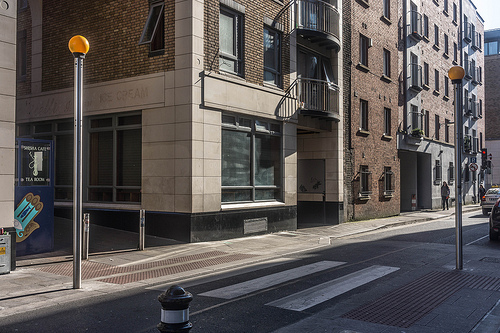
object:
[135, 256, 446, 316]
crosswalk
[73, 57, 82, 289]
pole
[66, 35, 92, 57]
ball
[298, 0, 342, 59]
balcony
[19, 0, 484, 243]
apartment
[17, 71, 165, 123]
sign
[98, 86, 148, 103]
ice cream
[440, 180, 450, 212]
woman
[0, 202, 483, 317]
sidewalk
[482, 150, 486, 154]
traffic-signal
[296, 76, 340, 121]
balcony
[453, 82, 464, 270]
post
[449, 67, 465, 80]
ball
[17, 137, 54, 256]
door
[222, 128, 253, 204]
window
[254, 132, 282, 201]
window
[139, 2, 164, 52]
window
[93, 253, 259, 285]
strip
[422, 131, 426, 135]
flowers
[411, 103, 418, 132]
window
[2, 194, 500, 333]
street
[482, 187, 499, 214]
car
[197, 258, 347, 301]
line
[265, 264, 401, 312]
line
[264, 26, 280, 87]
window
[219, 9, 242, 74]
window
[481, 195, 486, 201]
brake light